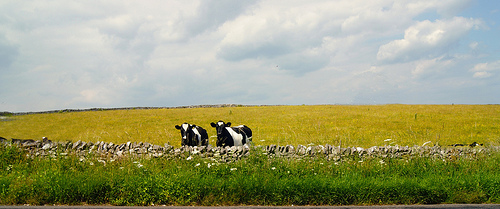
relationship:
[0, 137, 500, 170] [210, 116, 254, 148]
wall in front of cow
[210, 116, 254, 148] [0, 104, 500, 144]
cow in field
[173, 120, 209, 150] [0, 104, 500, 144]
cow in field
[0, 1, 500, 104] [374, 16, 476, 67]
sky has cloud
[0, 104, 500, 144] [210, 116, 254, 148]
field has cow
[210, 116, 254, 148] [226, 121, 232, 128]
cow has ear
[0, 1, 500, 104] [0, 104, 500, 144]
sky above field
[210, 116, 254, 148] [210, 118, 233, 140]
cow has head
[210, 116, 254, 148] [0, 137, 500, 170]
cow behind wall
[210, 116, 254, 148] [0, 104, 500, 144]
cow in front of field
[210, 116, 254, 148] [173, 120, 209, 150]
cow beside cow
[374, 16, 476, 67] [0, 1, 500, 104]
cloud in sky